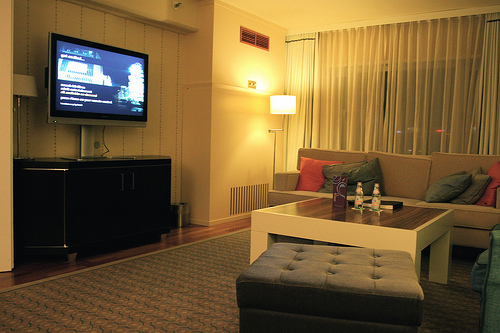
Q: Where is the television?
A: On the wall.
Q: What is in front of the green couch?
A: A gray foot rest.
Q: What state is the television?
A: Powered on.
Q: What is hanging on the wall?
A: A television.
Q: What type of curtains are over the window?
A: White sheer curtains.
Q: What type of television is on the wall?
A: A flat, black, and silver framed television.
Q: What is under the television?
A: A black entertainment stand.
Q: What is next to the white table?
A: A large square ottoman.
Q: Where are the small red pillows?
A: On the gray couch.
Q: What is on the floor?
A: Sofa.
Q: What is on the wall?
A: Tv.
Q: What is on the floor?
A: Footrest.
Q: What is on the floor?
A: Cabinet.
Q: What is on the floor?
A: Ottoman.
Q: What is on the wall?
A: Curtains.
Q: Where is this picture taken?
A: A hotel.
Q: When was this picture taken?
A: Night time.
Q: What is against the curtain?
A: A sofa.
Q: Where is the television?
A: On the wall.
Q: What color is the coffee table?
A: White.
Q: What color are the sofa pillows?
A: Orange, green and blue.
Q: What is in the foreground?
A: An ottoman.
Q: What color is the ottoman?
A: Blue.